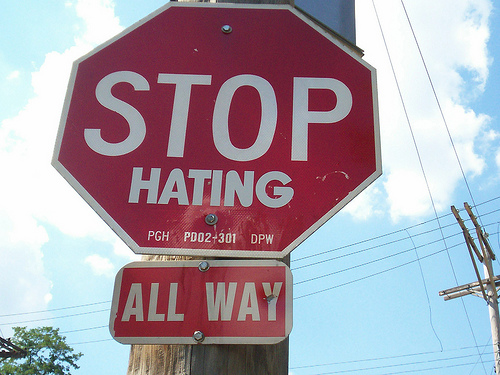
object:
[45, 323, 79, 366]
branch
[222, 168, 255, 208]
part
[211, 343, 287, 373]
part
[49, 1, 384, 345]
sign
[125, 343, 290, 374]
pole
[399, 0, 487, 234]
lines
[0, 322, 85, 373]
tree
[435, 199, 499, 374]
post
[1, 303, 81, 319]
wires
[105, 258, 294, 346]
sign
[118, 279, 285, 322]
all way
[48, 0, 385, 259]
sign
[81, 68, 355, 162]
stop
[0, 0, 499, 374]
sky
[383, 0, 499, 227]
clouds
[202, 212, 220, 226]
rivet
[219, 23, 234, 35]
bolt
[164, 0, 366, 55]
border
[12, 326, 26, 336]
leaves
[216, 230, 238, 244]
number